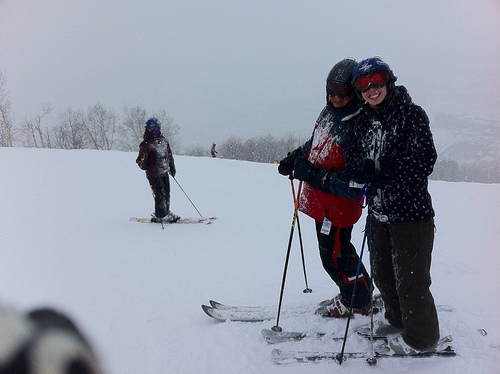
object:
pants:
[364, 214, 440, 348]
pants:
[314, 217, 373, 308]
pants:
[146, 172, 170, 216]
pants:
[211, 152, 216, 157]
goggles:
[356, 73, 395, 94]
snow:
[0, 143, 492, 368]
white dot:
[422, 216, 425, 218]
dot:
[393, 210, 405, 222]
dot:
[356, 110, 380, 124]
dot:
[409, 208, 414, 212]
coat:
[363, 85, 436, 223]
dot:
[407, 171, 422, 182]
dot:
[387, 134, 395, 139]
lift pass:
[320, 212, 332, 235]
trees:
[2, 91, 499, 182]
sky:
[5, 0, 500, 119]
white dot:
[397, 185, 400, 188]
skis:
[201, 299, 348, 362]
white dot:
[411, 218, 414, 221]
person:
[135, 117, 182, 223]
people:
[281, 57, 454, 357]